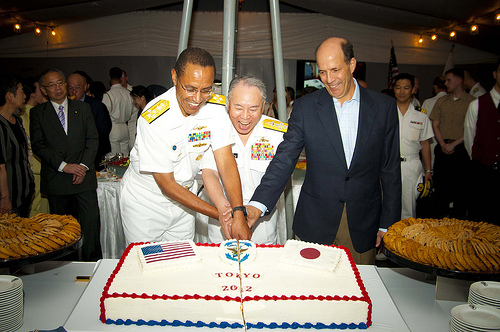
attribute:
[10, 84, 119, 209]
people — partying, gathered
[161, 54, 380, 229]
men — smiling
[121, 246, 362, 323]
cake — white, decorated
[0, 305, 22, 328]
plates — stacked, white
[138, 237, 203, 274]
flag — american, japanese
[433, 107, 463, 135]
shirt — brown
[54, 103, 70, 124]
tie — striped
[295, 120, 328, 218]
jacket — blue